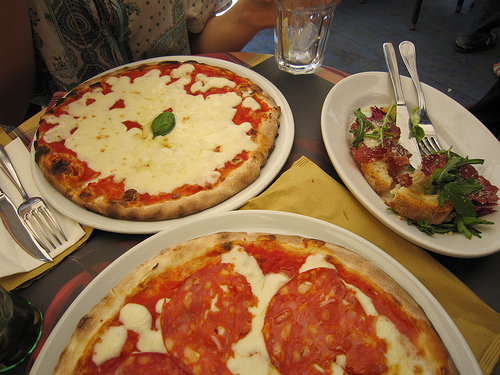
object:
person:
[1, 0, 274, 128]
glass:
[274, 1, 340, 76]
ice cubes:
[281, 7, 320, 66]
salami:
[263, 266, 386, 373]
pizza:
[50, 230, 460, 373]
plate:
[27, 209, 486, 374]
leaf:
[149, 110, 178, 140]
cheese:
[67, 74, 238, 196]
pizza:
[36, 59, 279, 220]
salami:
[355, 106, 409, 161]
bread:
[350, 104, 464, 228]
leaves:
[435, 177, 478, 223]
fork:
[0, 142, 69, 251]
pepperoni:
[160, 263, 258, 373]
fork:
[395, 39, 443, 157]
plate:
[319, 68, 499, 258]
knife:
[379, 41, 423, 176]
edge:
[34, 83, 101, 179]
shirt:
[26, 0, 234, 88]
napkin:
[1, 137, 88, 277]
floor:
[322, 4, 500, 105]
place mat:
[245, 156, 499, 374]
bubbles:
[35, 145, 83, 191]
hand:
[232, 0, 284, 30]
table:
[1, 51, 499, 372]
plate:
[31, 53, 299, 235]